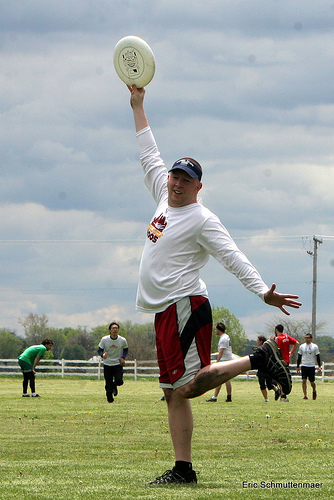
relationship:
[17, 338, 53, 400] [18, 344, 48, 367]
man wears shirt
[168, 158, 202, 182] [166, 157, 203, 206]
visor worn on head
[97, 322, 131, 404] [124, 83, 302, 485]
man runs toward man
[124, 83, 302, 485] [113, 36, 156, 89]
man holding frisbee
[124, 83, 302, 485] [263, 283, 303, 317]
man has hand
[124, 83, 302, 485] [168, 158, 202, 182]
man wearing visor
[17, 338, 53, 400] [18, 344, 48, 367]
man wearing shirt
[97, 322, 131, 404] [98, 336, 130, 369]
man wearing shirt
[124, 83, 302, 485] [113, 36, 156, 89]
man posing with frisbee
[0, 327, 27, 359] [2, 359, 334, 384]
tree outside of fence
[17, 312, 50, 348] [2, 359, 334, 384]
tree outside of fence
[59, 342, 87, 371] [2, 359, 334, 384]
tree outside of fence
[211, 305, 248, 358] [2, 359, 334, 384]
tree outside of fence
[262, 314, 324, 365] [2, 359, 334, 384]
tree outside of fence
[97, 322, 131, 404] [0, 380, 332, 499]
man running on field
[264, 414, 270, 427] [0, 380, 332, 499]
dandelion growing in field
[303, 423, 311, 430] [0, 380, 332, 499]
dandelion growing in field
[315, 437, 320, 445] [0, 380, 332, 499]
dandelion growing in field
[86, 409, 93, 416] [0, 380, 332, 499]
dandelion growing in field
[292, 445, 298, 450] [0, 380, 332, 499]
dandelion growing in field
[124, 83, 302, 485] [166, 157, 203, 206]
man has head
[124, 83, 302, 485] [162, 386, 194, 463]
man has leg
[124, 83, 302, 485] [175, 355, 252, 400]
man has leg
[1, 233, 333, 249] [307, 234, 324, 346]
power lines attached to pole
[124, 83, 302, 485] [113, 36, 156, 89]
man catching frisbee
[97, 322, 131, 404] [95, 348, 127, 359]
man wearing shirt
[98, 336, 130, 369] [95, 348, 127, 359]
shirt worn over shirt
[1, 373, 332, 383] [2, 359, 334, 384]
grass at base of fence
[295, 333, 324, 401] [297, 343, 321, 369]
man wearing shirt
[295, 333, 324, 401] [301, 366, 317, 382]
man wearing shorts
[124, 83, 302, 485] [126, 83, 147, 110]
man has hand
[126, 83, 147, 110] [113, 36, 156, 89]
hand holding frisbee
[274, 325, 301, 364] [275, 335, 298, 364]
man wearing shirt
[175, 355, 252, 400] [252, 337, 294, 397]
leg wearing shoe